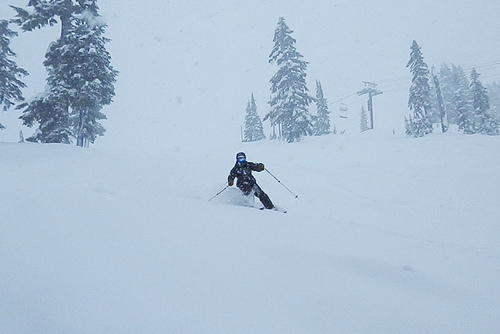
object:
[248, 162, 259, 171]
arm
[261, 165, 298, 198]
holding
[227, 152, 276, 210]
person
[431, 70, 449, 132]
tree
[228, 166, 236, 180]
arm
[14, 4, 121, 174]
pine tree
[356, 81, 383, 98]
tower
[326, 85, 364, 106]
cables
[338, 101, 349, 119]
chairlift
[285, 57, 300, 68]
snow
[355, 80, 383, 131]
lift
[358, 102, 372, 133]
pine tree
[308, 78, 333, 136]
pine tree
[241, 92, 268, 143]
pine tree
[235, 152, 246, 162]
head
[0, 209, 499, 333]
snow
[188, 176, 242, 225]
snow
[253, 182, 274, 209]
leg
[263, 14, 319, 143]
evergreen tree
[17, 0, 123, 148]
evergreen tree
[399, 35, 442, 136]
evergreen tree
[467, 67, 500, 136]
evergreen tree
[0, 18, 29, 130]
evergreen tree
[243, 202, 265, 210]
ski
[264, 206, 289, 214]
ski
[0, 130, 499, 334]
hill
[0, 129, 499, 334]
ground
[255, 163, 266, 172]
hand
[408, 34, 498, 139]
snow